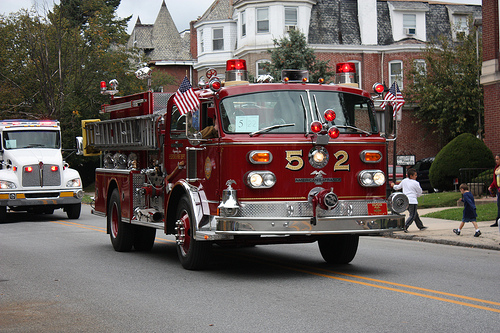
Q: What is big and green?
A: The tree.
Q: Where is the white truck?
A: In the street.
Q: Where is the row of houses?
A: Behind the fire truck.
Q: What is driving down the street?
A: A fire truck.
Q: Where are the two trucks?
A: In the street.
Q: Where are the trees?
A: In the background, by the homes.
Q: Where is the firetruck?
A: Middle of the road.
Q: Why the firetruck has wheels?
A: Help run.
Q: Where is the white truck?
A: Behind the firetruck.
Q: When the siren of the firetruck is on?
A: Emergency.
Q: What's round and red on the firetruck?
A: Lights.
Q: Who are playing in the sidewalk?
A: Kids.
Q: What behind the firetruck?
A: White truck.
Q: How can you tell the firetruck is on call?
A: Lights are on.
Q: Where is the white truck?
A: On the road.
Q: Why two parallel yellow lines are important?
A: No passing allowed.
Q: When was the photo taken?
A: Daytime.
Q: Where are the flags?
A: Firetruck.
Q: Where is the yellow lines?
A: Street.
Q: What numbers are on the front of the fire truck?
A: 5 2.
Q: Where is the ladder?
A: Side of the fire truck.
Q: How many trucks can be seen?
A: Two.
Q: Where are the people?
A: Sidewalk.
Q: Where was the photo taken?
A: At a parade.